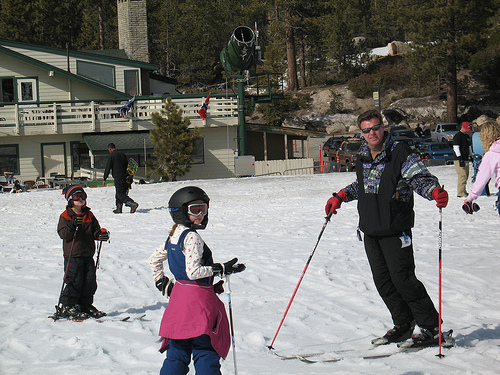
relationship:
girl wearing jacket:
[142, 181, 245, 287] [156, 279, 232, 359]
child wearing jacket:
[57, 178, 105, 254] [53, 209, 108, 254]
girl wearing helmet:
[142, 181, 245, 287] [160, 182, 218, 226]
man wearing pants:
[330, 102, 427, 236] [364, 231, 437, 331]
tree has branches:
[72, 0, 112, 49] [168, 56, 181, 77]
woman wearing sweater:
[477, 123, 500, 159] [462, 145, 499, 219]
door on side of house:
[43, 144, 66, 173] [0, 44, 313, 177]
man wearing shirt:
[99, 142, 145, 214] [101, 153, 129, 182]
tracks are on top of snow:
[108, 260, 146, 303] [219, 228, 272, 258]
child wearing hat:
[57, 178, 105, 254] [62, 184, 89, 194]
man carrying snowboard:
[99, 142, 145, 214] [124, 157, 139, 192]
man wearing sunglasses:
[330, 102, 427, 236] [357, 123, 385, 134]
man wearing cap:
[449, 120, 474, 195] [462, 121, 471, 133]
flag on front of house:
[198, 92, 215, 120] [0, 44, 313, 177]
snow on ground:
[219, 228, 272, 258] [235, 183, 319, 220]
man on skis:
[330, 102, 427, 236] [272, 327, 460, 367]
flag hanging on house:
[198, 92, 215, 120] [0, 44, 313, 177]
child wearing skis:
[57, 178, 105, 254] [46, 310, 150, 325]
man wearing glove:
[330, 102, 427, 236] [323, 184, 348, 213]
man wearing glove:
[330, 102, 427, 236] [432, 184, 448, 209]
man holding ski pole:
[330, 102, 427, 236] [264, 210, 343, 350]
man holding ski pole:
[330, 102, 427, 236] [435, 207, 448, 362]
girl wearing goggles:
[142, 181, 245, 287] [185, 200, 210, 216]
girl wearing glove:
[142, 181, 245, 287] [213, 254, 250, 277]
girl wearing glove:
[142, 181, 245, 287] [154, 275, 173, 295]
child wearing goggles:
[57, 178, 105, 254] [67, 190, 92, 200]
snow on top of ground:
[219, 228, 272, 258] [235, 183, 319, 220]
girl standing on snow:
[142, 181, 245, 287] [219, 228, 272, 258]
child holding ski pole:
[57, 178, 105, 254] [53, 218, 84, 320]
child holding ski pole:
[57, 178, 105, 254] [92, 226, 110, 269]